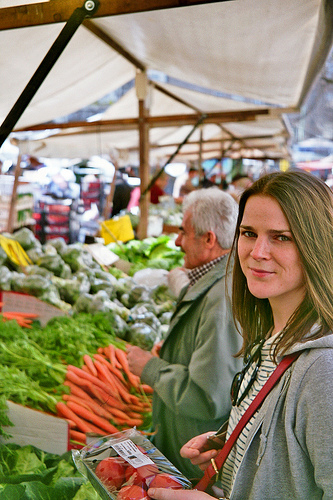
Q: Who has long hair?
A: A woman.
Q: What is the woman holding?
A: Tomatoes.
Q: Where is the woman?
A: At the market.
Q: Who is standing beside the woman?
A: A man.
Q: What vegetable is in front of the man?
A: Carrots.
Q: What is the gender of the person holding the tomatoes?
A: Female.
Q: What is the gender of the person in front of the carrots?
A: Male.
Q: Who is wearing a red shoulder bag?
A: The woman.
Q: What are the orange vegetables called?
A: Carrots.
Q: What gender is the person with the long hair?
A: Female.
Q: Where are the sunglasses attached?
A: To the woman's shirt.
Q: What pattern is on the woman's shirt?
A: Stripes.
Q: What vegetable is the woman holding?
A: Tomatoes.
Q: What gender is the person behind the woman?
A: Male.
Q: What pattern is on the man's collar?
A: Plaid.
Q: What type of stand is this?
A: A vegetable stand.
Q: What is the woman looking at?
A: Camera.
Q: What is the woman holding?
A: Tomatoes.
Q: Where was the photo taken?
A: Farmers market.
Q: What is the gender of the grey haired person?
A: Male.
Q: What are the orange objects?
A: Carrots.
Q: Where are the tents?
A: Above vegetables.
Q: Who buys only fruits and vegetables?
A: Vegans.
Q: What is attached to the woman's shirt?
A: Sunglasses.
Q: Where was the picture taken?
A: At a vegetable market.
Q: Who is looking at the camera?
A: The woman.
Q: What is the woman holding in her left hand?
A: Tomatoes.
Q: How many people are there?
A: Two.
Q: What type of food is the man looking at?
A: Carrots.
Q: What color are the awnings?
A: White.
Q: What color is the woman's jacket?
A: Gray.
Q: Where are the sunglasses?
A: Hanging on the woman's shirt.